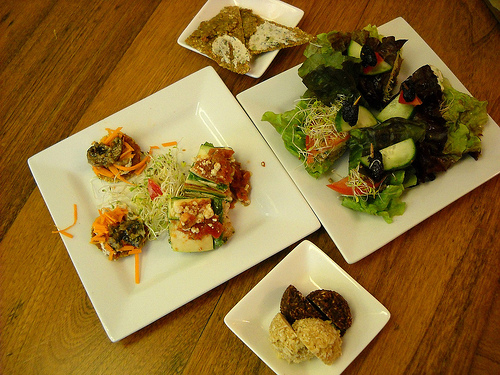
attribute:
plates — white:
[11, 4, 482, 372]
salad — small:
[250, 0, 463, 218]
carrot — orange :
[54, 206, 80, 237]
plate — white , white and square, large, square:
[28, 65, 321, 345]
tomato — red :
[299, 112, 343, 165]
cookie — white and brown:
[283, 286, 348, 332]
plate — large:
[235, 17, 499, 263]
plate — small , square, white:
[178, 0, 308, 79]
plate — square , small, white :
[227, 236, 391, 371]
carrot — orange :
[88, 206, 128, 241]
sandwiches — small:
[83, 124, 257, 277]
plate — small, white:
[172, 1, 309, 87]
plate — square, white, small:
[220, 233, 396, 373]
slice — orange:
[49, 202, 82, 238]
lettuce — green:
[113, 148, 187, 243]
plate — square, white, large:
[228, 10, 484, 272]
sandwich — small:
[368, 68, 440, 130]